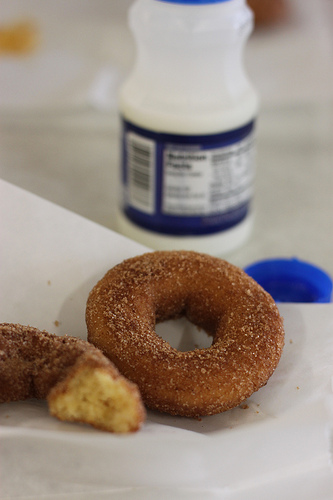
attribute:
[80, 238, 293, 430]
donut — brown, whole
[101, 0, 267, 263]
bottle — white, plastic, large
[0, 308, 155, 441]
donut — half eaten, bitten, half-eaten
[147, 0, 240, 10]
cap — blue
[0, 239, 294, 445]
donuts — brown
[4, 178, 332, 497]
box — white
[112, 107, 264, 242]
label — blue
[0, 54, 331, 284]
table — white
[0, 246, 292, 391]
sugar — brown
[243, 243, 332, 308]
object — blue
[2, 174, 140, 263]
surface — white